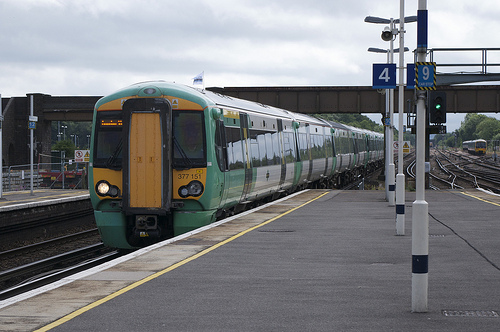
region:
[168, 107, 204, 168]
large tinted train window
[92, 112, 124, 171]
large tinted train window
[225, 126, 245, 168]
large tinted train window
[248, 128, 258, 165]
large tinted train window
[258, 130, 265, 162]
large tinted train window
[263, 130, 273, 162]
large tinted train window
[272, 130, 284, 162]
large tinted train window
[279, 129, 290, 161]
large tinted train window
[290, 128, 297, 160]
large tinted train window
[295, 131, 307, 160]
large tinted train window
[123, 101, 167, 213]
Yellow door to a train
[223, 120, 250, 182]
Long window of a train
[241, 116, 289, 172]
Long window of a train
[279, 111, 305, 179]
Long window of a train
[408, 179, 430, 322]
White and black post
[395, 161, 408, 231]
White and black post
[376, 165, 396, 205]
White and black post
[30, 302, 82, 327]
Part of yellow line on pavement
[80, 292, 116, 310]
Part of yellow line on pavement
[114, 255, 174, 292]
Part of yellow line on pavement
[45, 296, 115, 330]
Part of yellow line on pavement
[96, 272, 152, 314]
Part of yellow line on pavement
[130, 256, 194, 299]
Part of yellow line on pavement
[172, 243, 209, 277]
Part of yellow line on pavement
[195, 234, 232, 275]
Part of yellow line on pavement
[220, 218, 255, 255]
Part of yellow line on pavement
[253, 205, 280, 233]
Part of yellow line on pavement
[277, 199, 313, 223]
Part of yellow line on pavement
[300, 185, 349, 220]
Part of yellow line on pavement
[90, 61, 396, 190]
Green and yellow train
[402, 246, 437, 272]
blue section of white post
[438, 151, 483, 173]
criss cross train track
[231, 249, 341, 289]
gray color on platform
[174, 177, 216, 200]
curved light at front of train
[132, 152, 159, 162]
handles on yellow door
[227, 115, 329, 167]
shine on side windows of train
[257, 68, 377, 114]
black iron bridge in the air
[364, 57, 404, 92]
white number on blue sign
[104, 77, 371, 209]
large green train on tracks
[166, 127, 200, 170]
long black windshield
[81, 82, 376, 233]
a green and yellow train pulling into the station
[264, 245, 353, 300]
grey asphalt of the train platform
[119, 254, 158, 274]
grey concrete of the platform divider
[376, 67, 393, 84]
white number on a blue sign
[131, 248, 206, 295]
yelow line painted on the asphalt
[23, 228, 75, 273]
an empty set of train tracks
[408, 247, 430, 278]
blue stripe on the white pole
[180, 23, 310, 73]
white cloudy skies over the train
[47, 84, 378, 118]
metal bridge over the train tracks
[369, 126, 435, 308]
several white poles on the train platform